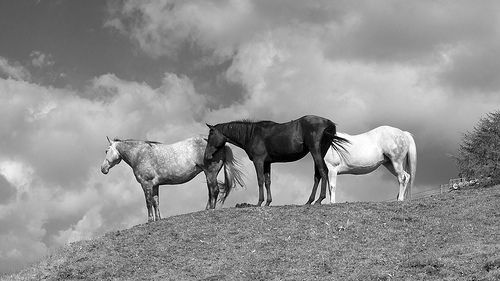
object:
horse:
[100, 132, 249, 223]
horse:
[205, 115, 353, 207]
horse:
[323, 125, 415, 204]